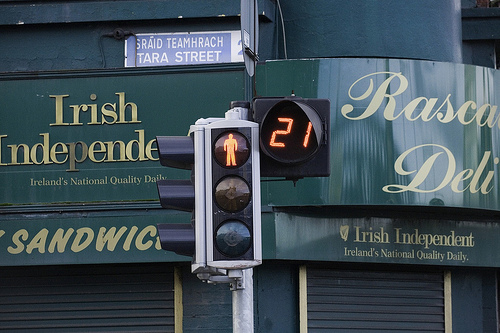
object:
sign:
[124, 30, 245, 67]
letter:
[6, 228, 29, 255]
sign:
[2, 209, 194, 267]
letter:
[25, 227, 49, 254]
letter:
[47, 227, 73, 253]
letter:
[68, 227, 95, 252]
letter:
[95, 226, 127, 252]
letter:
[122, 225, 138, 251]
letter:
[135, 225, 158, 250]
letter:
[339, 72, 408, 120]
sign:
[257, 58, 500, 210]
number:
[271, 117, 312, 148]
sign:
[253, 97, 330, 175]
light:
[213, 132, 249, 168]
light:
[215, 178, 252, 214]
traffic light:
[156, 101, 264, 291]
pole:
[221, 101, 255, 333]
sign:
[0, 64, 248, 208]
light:
[214, 221, 253, 258]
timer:
[251, 98, 331, 178]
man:
[224, 132, 239, 167]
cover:
[154, 133, 195, 172]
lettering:
[381, 143, 454, 194]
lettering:
[29, 174, 167, 187]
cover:
[154, 181, 194, 212]